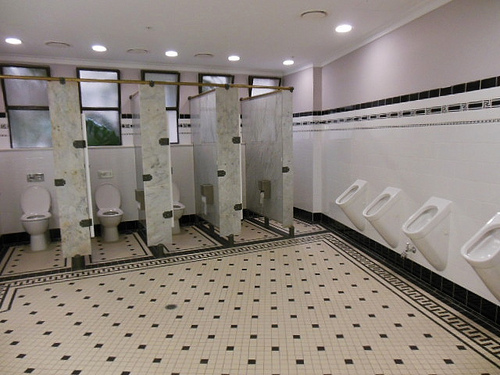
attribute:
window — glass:
[55, 54, 139, 148]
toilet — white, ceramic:
[16, 183, 53, 251]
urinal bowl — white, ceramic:
[334, 172, 372, 227]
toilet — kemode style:
[15, 187, 56, 250]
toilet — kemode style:
[95, 184, 127, 242]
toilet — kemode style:
[169, 181, 191, 235]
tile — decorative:
[403, 312, 418, 321]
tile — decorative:
[405, 339, 421, 354]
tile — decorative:
[251, 297, 261, 304]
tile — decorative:
[182, 295, 192, 305]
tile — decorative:
[206, 332, 215, 344]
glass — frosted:
[8, 107, 50, 147]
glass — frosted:
[2, 62, 48, 104]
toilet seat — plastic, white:
[19, 210, 55, 224]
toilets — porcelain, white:
[12, 157, 204, 256]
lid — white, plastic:
[18, 181, 49, 217]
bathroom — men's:
[13, 80, 493, 372]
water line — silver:
[398, 238, 418, 262]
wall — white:
[281, 0, 499, 337]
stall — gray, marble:
[129, 85, 174, 247]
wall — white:
[0, 56, 282, 246]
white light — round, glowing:
[283, 59, 295, 68]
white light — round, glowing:
[331, 23, 353, 34]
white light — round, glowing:
[4, 38, 23, 48]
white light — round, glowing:
[91, 44, 106, 54]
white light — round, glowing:
[163, 46, 181, 58]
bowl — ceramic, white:
[20, 208, 54, 254]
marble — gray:
[129, 79, 175, 253]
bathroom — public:
[2, 4, 497, 373]